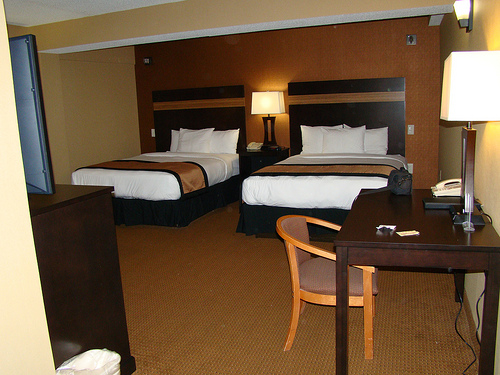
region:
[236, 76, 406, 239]
queen sized black bed with white sheets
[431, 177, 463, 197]
off white desk phone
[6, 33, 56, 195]
back of black flat screen TV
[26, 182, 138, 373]
chocolate brown TV stand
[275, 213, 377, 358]
wooden chair with salmon seat cushion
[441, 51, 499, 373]
black power cord for metal table lamp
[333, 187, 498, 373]
chocolate brown table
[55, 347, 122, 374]
white trash can with plastic liner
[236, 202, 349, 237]
black fabric bed skirt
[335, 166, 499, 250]
dark grey purse is on the table top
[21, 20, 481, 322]
A nicely decorated hotel room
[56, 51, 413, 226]
Two full size beds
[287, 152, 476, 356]
Writing desk and chair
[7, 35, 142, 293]
Flat screen television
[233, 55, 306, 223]
Table lamp on the night stand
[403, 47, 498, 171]
Desk lamp whit white shade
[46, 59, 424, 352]
Neat and clean hotel room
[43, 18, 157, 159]
Yellow wall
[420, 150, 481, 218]
Phone on the desk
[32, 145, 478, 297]
Brown wooden furniture in the room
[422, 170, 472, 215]
a telephone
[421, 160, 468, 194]
a telephone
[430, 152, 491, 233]
a telephone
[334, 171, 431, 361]
A table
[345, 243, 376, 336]
A table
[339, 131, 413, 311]
A table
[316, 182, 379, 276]
A table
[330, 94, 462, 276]
A table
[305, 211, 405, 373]
A table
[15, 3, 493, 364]
a hotel room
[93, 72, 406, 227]
two identical beds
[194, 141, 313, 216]
small table between beds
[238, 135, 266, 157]
beige phone on small table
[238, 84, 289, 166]
lit lamp on table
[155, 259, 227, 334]
brown carpet with small pattern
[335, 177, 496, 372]
a dark brown table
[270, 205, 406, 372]
chair beside the table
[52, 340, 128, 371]
trash can with liner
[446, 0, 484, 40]
light on the wall